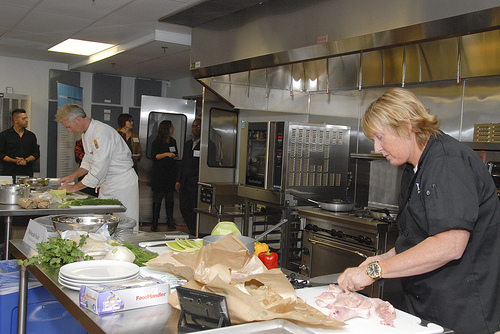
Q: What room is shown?
A: It is a kitchen.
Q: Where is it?
A: This is at the kitchen.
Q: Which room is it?
A: It is a kitchen.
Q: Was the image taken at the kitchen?
A: Yes, it was taken in the kitchen.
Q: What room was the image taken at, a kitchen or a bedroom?
A: It was taken at a kitchen.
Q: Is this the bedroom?
A: No, it is the kitchen.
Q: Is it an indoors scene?
A: Yes, it is indoors.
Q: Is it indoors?
A: Yes, it is indoors.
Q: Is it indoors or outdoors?
A: It is indoors.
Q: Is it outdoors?
A: No, it is indoors.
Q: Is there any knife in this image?
A: Yes, there is a knife.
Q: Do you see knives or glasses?
A: Yes, there is a knife.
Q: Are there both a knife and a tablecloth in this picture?
A: No, there is a knife but no tablecloths.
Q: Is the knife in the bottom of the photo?
A: Yes, the knife is in the bottom of the image.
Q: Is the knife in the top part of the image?
A: No, the knife is in the bottom of the image.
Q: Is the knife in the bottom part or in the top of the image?
A: The knife is in the bottom of the image.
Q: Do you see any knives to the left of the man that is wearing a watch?
A: Yes, there is a knife to the left of the man.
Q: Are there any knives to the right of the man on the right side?
A: No, the knife is to the left of the man.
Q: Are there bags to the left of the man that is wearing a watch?
A: No, there is a knife to the left of the man.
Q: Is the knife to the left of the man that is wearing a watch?
A: Yes, the knife is to the left of the man.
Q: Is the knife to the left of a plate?
A: No, the knife is to the left of the man.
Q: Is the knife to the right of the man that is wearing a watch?
A: No, the knife is to the left of the man.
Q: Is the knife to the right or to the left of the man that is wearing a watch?
A: The knife is to the left of the man.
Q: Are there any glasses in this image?
A: No, there are no glasses.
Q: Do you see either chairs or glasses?
A: No, there are no glasses or chairs.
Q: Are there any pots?
A: Yes, there is a pot.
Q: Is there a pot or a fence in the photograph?
A: Yes, there is a pot.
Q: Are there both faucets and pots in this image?
A: No, there is a pot but no faucets.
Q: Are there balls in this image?
A: No, there are no balls.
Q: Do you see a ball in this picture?
A: No, there are no balls.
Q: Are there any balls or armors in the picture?
A: No, there are no balls or armors.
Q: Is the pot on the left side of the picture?
A: Yes, the pot is on the left of the image.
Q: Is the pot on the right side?
A: No, the pot is on the left of the image.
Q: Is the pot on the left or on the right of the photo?
A: The pot is on the left of the image.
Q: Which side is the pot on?
A: The pot is on the left of the image.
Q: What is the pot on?
A: The pot is on the table.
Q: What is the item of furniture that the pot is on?
A: The piece of furniture is a table.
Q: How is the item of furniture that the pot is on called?
A: The piece of furniture is a table.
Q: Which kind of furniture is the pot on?
A: The pot is on the table.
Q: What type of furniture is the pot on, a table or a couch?
A: The pot is on a table.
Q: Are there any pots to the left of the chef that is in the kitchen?
A: Yes, there is a pot to the left of the chef.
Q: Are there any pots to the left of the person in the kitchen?
A: Yes, there is a pot to the left of the chef.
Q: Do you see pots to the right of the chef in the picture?
A: No, the pot is to the left of the chef.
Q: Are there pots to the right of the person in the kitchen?
A: No, the pot is to the left of the chef.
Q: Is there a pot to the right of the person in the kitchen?
A: No, the pot is to the left of the chef.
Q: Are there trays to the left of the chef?
A: No, there is a pot to the left of the chef.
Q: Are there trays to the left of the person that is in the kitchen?
A: No, there is a pot to the left of the chef.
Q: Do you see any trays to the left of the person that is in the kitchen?
A: No, there is a pot to the left of the chef.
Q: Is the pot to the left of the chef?
A: Yes, the pot is to the left of the chef.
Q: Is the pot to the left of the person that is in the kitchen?
A: Yes, the pot is to the left of the chef.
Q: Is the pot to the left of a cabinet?
A: No, the pot is to the left of the chef.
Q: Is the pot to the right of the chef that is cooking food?
A: No, the pot is to the left of the chef.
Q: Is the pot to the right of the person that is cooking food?
A: No, the pot is to the left of the chef.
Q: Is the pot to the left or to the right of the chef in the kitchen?
A: The pot is to the left of the chef.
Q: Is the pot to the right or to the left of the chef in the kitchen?
A: The pot is to the left of the chef.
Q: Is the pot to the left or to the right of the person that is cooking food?
A: The pot is to the left of the chef.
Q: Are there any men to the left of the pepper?
A: No, the man is to the right of the pepper.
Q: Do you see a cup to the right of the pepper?
A: No, there is a man to the right of the pepper.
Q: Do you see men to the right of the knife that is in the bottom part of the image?
A: Yes, there is a man to the right of the knife.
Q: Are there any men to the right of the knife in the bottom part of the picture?
A: Yes, there is a man to the right of the knife.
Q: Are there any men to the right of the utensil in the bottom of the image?
A: Yes, there is a man to the right of the knife.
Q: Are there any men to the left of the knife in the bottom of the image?
A: No, the man is to the right of the knife.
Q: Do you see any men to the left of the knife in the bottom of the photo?
A: No, the man is to the right of the knife.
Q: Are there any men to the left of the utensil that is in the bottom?
A: No, the man is to the right of the knife.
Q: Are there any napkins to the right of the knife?
A: No, there is a man to the right of the knife.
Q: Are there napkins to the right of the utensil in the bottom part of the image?
A: No, there is a man to the right of the knife.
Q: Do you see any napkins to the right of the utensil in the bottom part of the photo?
A: No, there is a man to the right of the knife.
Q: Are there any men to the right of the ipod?
A: Yes, there is a man to the right of the ipod.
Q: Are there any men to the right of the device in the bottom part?
A: Yes, there is a man to the right of the ipod.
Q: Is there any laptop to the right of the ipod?
A: No, there is a man to the right of the ipod.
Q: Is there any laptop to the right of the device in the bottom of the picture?
A: No, there is a man to the right of the ipod.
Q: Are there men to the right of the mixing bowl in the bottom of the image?
A: Yes, there is a man to the right of the mixing bowl.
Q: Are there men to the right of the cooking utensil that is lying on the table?
A: Yes, there is a man to the right of the mixing bowl.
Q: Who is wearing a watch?
A: The man is wearing a watch.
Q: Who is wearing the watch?
A: The man is wearing a watch.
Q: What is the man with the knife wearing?
A: The man is wearing a watch.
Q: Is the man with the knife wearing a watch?
A: Yes, the man is wearing a watch.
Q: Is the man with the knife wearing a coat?
A: No, the man is wearing a watch.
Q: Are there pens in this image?
A: No, there are no pens.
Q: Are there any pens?
A: No, there are no pens.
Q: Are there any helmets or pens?
A: No, there are no pens or helmets.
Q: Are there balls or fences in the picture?
A: No, there are no fences or balls.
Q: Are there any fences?
A: No, there are no fences.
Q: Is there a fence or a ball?
A: No, there are no fences or balls.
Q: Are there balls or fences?
A: No, there are no fences or balls.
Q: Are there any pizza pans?
A: No, there are no pizza pans.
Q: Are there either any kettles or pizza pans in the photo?
A: No, there are no pizza pans or kettles.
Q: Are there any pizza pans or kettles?
A: No, there are no pizza pans or kettles.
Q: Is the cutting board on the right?
A: Yes, the cutting board is on the right of the image.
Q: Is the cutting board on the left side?
A: No, the cutting board is on the right of the image.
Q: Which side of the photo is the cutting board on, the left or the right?
A: The cutting board is on the right of the image.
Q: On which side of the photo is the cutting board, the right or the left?
A: The cutting board is on the right of the image.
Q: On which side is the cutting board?
A: The cutting board is on the right of the image.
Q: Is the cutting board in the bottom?
A: Yes, the cutting board is in the bottom of the image.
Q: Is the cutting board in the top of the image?
A: No, the cutting board is in the bottom of the image.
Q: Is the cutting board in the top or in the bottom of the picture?
A: The cutting board is in the bottom of the image.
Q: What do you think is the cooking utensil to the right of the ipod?
A: The cooking utensil is a cutting board.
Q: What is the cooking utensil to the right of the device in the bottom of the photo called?
A: The cooking utensil is a cutting board.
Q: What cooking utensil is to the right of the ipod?
A: The cooking utensil is a cutting board.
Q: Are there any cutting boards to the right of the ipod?
A: Yes, there is a cutting board to the right of the ipod.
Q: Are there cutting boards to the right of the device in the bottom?
A: Yes, there is a cutting board to the right of the ipod.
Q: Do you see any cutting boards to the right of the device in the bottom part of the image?
A: Yes, there is a cutting board to the right of the ipod.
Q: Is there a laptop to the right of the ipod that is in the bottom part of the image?
A: No, there is a cutting board to the right of the ipod.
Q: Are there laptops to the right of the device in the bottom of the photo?
A: No, there is a cutting board to the right of the ipod.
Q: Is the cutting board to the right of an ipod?
A: Yes, the cutting board is to the right of an ipod.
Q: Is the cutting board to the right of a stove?
A: No, the cutting board is to the right of an ipod.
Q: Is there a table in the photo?
A: Yes, there is a table.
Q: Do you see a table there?
A: Yes, there is a table.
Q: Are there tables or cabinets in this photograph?
A: Yes, there is a table.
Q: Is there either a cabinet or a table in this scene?
A: Yes, there is a table.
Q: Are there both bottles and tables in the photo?
A: No, there is a table but no bottles.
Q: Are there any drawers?
A: No, there are no drawers.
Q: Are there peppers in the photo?
A: Yes, there is a pepper.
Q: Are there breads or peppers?
A: Yes, there is a pepper.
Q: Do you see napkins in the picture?
A: No, there are no napkins.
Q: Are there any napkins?
A: No, there are no napkins.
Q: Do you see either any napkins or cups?
A: No, there are no napkins or cups.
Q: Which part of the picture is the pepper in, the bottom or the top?
A: The pepper is in the bottom of the image.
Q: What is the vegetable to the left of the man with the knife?
A: The vegetable is a pepper.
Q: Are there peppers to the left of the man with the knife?
A: Yes, there is a pepper to the left of the man.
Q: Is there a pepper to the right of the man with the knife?
A: No, the pepper is to the left of the man.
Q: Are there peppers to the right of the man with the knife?
A: No, the pepper is to the left of the man.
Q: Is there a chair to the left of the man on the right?
A: No, there is a pepper to the left of the man.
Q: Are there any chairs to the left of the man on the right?
A: No, there is a pepper to the left of the man.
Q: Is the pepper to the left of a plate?
A: No, the pepper is to the left of a man.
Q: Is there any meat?
A: Yes, there is meat.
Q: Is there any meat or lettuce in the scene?
A: Yes, there is meat.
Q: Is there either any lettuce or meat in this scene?
A: Yes, there is meat.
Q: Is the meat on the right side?
A: Yes, the meat is on the right of the image.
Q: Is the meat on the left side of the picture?
A: No, the meat is on the right of the image.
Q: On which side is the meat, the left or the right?
A: The meat is on the right of the image.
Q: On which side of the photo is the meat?
A: The meat is on the right of the image.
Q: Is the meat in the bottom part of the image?
A: Yes, the meat is in the bottom of the image.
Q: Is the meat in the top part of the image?
A: No, the meat is in the bottom of the image.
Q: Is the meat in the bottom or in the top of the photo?
A: The meat is in the bottom of the image.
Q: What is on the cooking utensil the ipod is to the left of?
A: The meat is on the cutting board.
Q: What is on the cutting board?
A: The meat is on the cutting board.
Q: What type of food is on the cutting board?
A: The food is meat.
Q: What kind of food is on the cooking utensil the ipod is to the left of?
A: The food is meat.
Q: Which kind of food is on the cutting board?
A: The food is meat.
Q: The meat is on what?
A: The meat is on the cutting board.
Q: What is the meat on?
A: The meat is on the cutting board.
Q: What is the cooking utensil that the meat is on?
A: The cooking utensil is a cutting board.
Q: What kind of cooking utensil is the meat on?
A: The meat is on the cutting board.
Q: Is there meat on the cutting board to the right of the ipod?
A: Yes, there is meat on the cutting board.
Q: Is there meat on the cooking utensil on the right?
A: Yes, there is meat on the cutting board.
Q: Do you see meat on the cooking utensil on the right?
A: Yes, there is meat on the cutting board.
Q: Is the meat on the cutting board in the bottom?
A: Yes, the meat is on the cutting board.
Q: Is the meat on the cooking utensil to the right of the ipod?
A: Yes, the meat is on the cutting board.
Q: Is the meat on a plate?
A: No, the meat is on the cutting board.